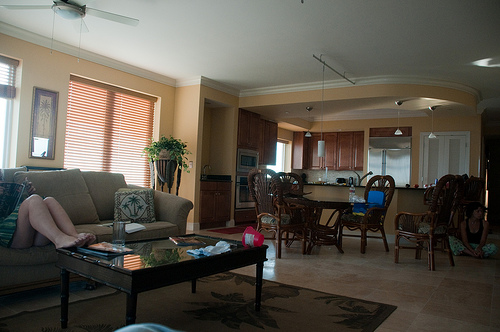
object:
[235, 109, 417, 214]
kitchen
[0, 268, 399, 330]
rug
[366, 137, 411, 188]
refrigerator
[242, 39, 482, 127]
ceiling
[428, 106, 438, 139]
light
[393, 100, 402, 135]
light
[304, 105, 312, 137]
light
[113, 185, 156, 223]
pillow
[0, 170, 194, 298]
couch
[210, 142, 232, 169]
tile wall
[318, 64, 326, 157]
light fixture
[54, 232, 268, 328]
coffee table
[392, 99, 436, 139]
two lights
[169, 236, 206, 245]
booklet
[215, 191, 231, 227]
cabinets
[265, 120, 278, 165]
cabinets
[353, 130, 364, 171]
cabinets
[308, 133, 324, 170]
wood cabinets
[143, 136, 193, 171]
plant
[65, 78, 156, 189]
window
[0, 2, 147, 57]
fan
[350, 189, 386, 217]
baby seat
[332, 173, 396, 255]
baby chair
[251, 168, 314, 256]
baby chair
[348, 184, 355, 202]
bottle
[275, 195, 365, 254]
table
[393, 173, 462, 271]
chairs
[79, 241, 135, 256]
magazines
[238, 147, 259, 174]
microwave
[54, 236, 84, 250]
feet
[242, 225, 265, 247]
object